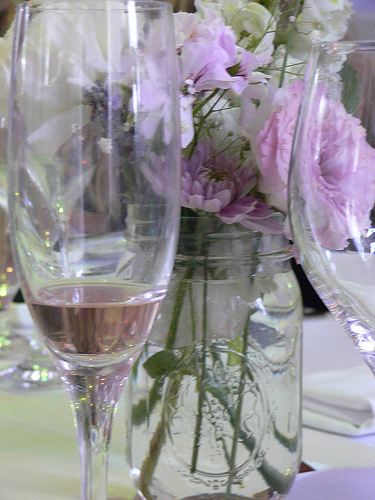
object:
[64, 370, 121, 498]
stem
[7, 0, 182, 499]
champagne glass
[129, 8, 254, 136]
flower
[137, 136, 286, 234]
flower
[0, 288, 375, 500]
cloth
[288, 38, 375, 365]
wine glass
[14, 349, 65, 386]
wine glass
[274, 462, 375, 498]
tablecloth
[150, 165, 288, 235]
flower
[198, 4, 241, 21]
flower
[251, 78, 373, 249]
flower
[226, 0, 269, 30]
flower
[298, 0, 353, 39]
flower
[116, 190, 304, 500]
bottle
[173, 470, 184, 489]
water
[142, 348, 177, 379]
leaf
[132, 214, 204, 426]
stem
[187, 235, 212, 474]
stem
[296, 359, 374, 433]
napkin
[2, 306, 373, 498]
table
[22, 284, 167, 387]
champagne